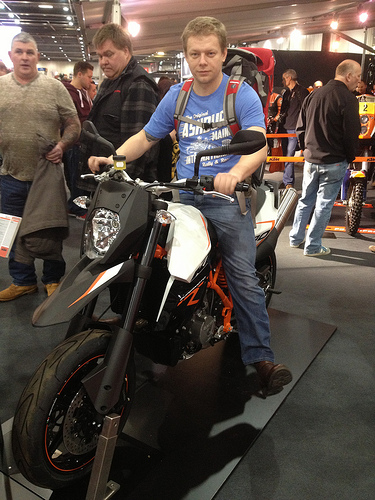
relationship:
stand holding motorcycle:
[0, 302, 342, 498] [7, 117, 311, 489]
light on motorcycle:
[84, 206, 120, 259] [7, 117, 311, 489]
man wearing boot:
[87, 15, 294, 400] [251, 355, 296, 399]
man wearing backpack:
[87, 15, 294, 400] [173, 45, 282, 146]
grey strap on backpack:
[175, 114, 235, 131] [173, 45, 282, 146]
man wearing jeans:
[87, 15, 294, 400] [163, 173, 315, 361]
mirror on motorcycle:
[225, 128, 266, 156] [7, 117, 311, 489]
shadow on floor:
[218, 418, 250, 454] [11, 186, 357, 490]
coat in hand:
[9, 134, 71, 269] [239, 88, 284, 213]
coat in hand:
[9, 134, 69, 289] [49, 89, 89, 171]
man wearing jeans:
[87, 15, 294, 400] [287, 152, 350, 248]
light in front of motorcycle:
[84, 205, 120, 259] [27, 162, 309, 489]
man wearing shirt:
[87, 15, 294, 400] [142, 70, 265, 193]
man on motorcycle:
[87, 15, 294, 400] [39, 143, 275, 415]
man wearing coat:
[284, 39, 367, 189] [294, 72, 371, 167]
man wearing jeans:
[284, 39, 363, 262] [214, 201, 288, 400]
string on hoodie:
[75, 87, 86, 110] [61, 80, 96, 126]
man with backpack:
[87, 15, 294, 400] [173, 45, 278, 226]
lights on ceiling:
[251, 8, 373, 44] [78, 1, 349, 50]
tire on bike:
[340, 175, 364, 237] [336, 89, 370, 234]